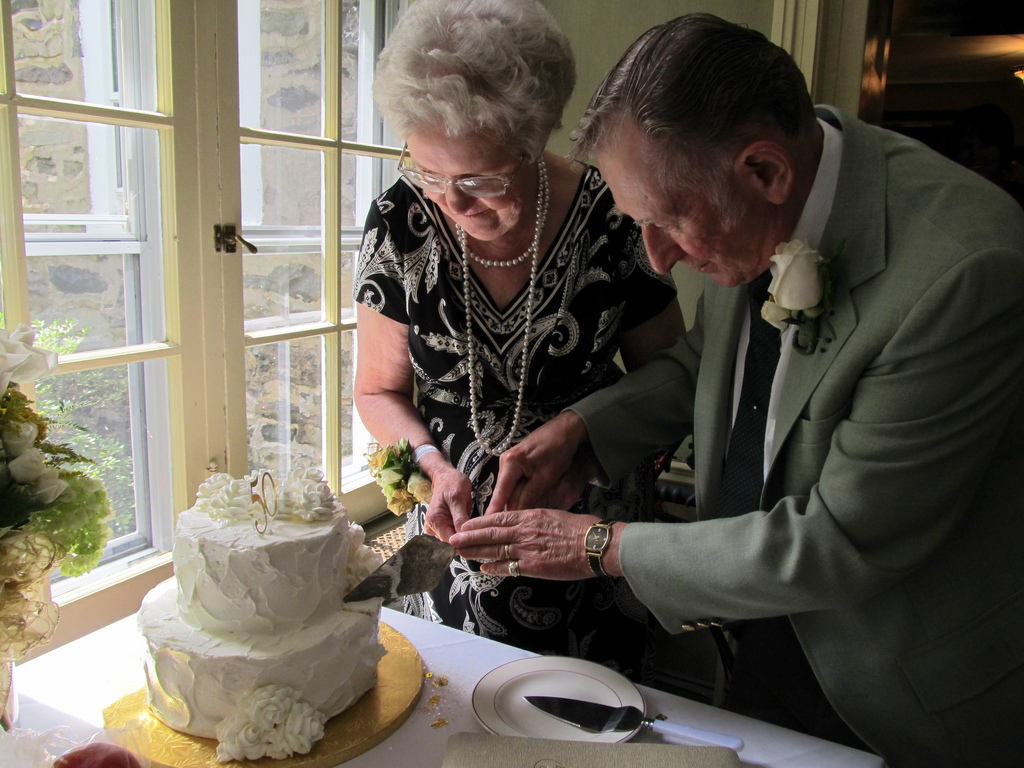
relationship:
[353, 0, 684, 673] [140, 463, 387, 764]
woman cutting cake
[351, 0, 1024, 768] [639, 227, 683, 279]
couple has nose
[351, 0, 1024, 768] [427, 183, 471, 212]
couple has nose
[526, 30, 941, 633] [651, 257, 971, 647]
man wearing suit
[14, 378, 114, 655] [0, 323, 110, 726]
bouquet of bouquet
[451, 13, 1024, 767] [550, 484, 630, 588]
man wearing watch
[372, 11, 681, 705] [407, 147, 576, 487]
woman wearing pearls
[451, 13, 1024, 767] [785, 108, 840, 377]
man wearing shirt collar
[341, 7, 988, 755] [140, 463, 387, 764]
couple cutting cake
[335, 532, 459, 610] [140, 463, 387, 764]
utensil for serving cake